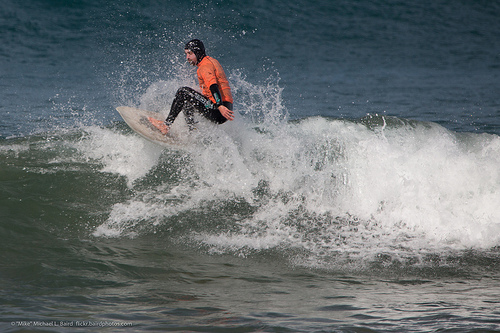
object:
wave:
[2, 109, 499, 278]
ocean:
[2, 2, 500, 333]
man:
[146, 39, 235, 135]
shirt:
[196, 56, 233, 109]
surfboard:
[114, 106, 180, 149]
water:
[2, 3, 498, 131]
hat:
[184, 39, 207, 65]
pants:
[163, 86, 233, 135]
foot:
[145, 116, 170, 136]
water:
[1, 245, 499, 333]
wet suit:
[165, 56, 234, 133]